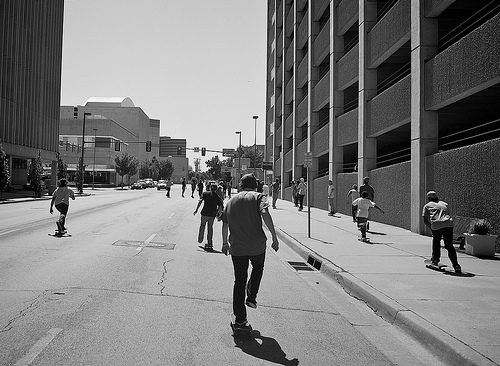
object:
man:
[217, 172, 282, 333]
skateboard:
[228, 312, 254, 339]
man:
[422, 190, 467, 278]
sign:
[301, 146, 317, 171]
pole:
[302, 164, 317, 241]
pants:
[228, 252, 266, 321]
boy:
[348, 190, 386, 243]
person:
[47, 176, 78, 232]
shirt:
[52, 183, 73, 207]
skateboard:
[419, 254, 459, 276]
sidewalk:
[257, 192, 500, 365]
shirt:
[422, 199, 458, 233]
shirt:
[351, 196, 379, 219]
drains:
[287, 261, 316, 271]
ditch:
[308, 259, 324, 272]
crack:
[155, 255, 173, 296]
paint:
[10, 327, 67, 365]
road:
[0, 178, 468, 365]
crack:
[332, 271, 395, 324]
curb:
[259, 221, 492, 365]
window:
[369, 115, 412, 169]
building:
[263, 0, 500, 250]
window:
[340, 140, 357, 171]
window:
[372, 32, 414, 94]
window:
[436, 76, 500, 153]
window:
[309, 50, 330, 83]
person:
[416, 186, 465, 272]